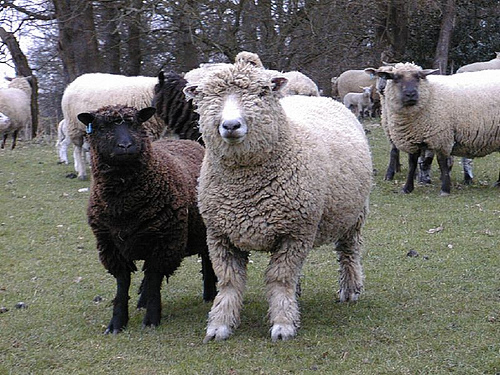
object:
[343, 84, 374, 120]
sheep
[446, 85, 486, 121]
wool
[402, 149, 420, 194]
legs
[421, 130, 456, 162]
wall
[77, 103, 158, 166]
head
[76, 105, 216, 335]
brown sheep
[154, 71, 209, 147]
brown sheep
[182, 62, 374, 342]
large sheep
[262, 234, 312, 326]
leg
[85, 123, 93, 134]
blue tag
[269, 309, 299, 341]
hoof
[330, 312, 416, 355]
ground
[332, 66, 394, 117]
sheep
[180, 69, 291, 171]
sheep head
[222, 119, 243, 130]
nose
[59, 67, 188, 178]
sheep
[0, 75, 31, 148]
sheep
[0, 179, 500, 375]
field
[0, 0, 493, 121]
trees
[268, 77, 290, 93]
ear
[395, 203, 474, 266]
ground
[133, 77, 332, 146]
black fence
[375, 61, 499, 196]
sheep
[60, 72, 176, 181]
sheep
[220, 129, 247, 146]
mouth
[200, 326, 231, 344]
hoofs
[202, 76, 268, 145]
face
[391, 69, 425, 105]
face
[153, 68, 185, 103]
face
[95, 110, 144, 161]
face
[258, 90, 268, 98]
eye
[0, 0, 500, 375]
camera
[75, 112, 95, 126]
ear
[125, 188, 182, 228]
wool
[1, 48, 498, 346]
flock